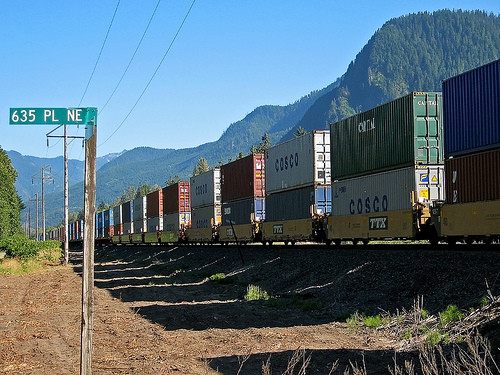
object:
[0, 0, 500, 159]
sky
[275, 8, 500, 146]
hills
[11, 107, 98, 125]
green/whitesign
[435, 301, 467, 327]
grass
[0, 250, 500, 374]
dirt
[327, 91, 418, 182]
rail car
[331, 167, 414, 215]
rail car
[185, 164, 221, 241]
cartainer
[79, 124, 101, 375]
pole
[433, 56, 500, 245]
train car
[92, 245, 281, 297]
shadow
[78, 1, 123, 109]
lines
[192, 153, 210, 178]
trees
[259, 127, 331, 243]
train car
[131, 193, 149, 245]
train car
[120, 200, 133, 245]
train car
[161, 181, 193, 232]
double unit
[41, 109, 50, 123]
lettering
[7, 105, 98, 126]
street sign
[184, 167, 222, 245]
car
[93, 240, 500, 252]
tracks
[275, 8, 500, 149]
mountain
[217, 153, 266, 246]
train car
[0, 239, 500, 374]
ground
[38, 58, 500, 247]
train